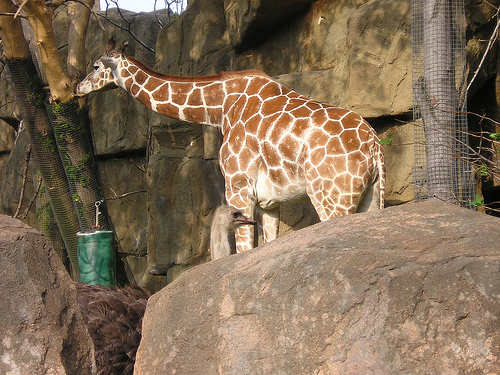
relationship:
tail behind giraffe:
[369, 143, 400, 211] [54, 32, 412, 274]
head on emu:
[210, 203, 255, 228] [70, 204, 255, 375]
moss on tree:
[33, 99, 111, 288] [4, 2, 154, 304]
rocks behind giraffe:
[129, 8, 498, 373] [69, 34, 389, 266]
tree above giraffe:
[92, 2, 196, 54] [69, 34, 389, 266]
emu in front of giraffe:
[70, 202, 257, 373] [69, 34, 389, 266]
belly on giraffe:
[257, 167, 310, 210] [69, 34, 389, 266]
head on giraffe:
[72, 35, 133, 99] [71, 50, 395, 246]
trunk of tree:
[41, 99, 136, 292] [412, 1, 464, 205]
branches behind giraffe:
[425, 100, 498, 172] [54, 32, 412, 274]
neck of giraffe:
[117, 53, 226, 124] [71, 50, 395, 246]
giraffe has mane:
[69, 34, 389, 266] [124, 55, 274, 82]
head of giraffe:
[76, 40, 142, 106] [69, 34, 389, 266]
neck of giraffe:
[115, 61, 231, 131] [71, 50, 395, 246]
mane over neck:
[114, 43, 274, 93] [151, 50, 241, 162]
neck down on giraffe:
[115, 61, 231, 131] [71, 50, 395, 246]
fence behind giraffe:
[394, 2, 497, 214] [70, 29, 389, 246]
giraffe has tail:
[69, 34, 389, 266] [376, 144, 386, 209]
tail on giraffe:
[376, 144, 386, 209] [69, 34, 389, 266]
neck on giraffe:
[115, 61, 231, 131] [68, 55, 140, 99]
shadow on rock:
[246, 24, 323, 81] [306, 47, 387, 75]